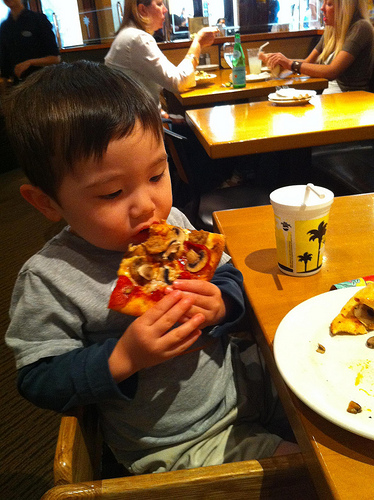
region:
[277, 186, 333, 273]
CUP ON THE TABLE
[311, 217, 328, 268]
PALM TREE ON THE CUP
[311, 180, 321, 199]
STRAW IN THE CUP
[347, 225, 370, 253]
TABLE MADE OUT OF WOOD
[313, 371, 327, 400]
WHITE PLATE ON THE TABLE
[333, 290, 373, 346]
FOOD ON THE PLATE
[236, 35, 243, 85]
BOTTLE ON THE TABLE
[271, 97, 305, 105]
PLATES STACKED ON TABLE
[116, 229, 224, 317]
BOY HOLDING A SLICE OF PIZZA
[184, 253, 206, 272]
MUSHROOMS ON THE PIZZA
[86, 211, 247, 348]
pepperoni is on the pizza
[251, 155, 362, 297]
plastic cup has a straw in it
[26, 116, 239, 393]
little boy is eating pizza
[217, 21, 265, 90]
bottle of water on the table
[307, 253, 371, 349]
pizza is sitting on the plate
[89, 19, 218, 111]
woman wearing white shirt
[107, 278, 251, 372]
the little boy's hands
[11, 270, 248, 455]
little boy wearing gray shirt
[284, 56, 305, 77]
bracelets on the womans wrist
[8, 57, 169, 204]
the boy has dark hair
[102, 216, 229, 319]
Slice of pizza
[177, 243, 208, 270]
Slice of mushroom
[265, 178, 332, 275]
Cup with a straw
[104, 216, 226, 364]
Child's hands holding pizza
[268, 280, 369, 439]
Plate with food on it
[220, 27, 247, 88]
Green bottle with wine glass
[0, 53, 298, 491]
Child eating a slice of pizza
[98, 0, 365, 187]
Two women sitting a table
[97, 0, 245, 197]
Woman wearing white shirt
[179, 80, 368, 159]
Stack of dishes on table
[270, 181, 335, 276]
Yellow and white cup.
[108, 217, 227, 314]
A piece of pizza.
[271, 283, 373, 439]
A white dinner plate.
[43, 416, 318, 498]
A wooden high chair.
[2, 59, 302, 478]
A little boy eating.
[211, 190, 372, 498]
A light wood table.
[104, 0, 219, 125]
A woman wearing white.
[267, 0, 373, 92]
A woman wearing brown.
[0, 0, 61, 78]
A person in a black shirt.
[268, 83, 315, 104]
A pile of dishes.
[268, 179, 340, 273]
a small white cup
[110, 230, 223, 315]
a piece of pizza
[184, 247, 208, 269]
a mushroom on the pizza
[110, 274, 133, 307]
a slice of pepperoni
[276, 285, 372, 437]
a white plate on the table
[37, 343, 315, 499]
a wooden high chair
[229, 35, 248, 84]
a green bottle on the table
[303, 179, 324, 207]
a white bent straw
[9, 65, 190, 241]
a little boy with brown hair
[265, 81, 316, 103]
a stack of white plates